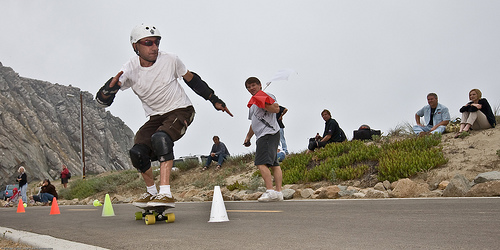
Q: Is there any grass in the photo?
A: Yes, there is grass.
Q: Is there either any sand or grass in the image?
A: Yes, there is grass.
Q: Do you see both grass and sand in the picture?
A: No, there is grass but no sand.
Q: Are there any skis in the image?
A: No, there are no skis.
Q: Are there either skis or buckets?
A: No, there are no skis or buckets.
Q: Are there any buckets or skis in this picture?
A: No, there are no skis or buckets.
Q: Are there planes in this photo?
A: No, there are no planes.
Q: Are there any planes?
A: No, there are no planes.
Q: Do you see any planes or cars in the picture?
A: No, there are no planes or cars.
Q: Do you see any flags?
A: Yes, there is a flag.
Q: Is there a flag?
A: Yes, there is a flag.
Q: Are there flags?
A: Yes, there is a flag.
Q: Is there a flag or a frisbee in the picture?
A: Yes, there is a flag.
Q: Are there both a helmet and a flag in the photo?
A: Yes, there are both a flag and a helmet.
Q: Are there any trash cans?
A: No, there are no trash cans.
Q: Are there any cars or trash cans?
A: No, there are no trash cans or cars.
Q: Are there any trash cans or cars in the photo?
A: No, there are no trash cans or cars.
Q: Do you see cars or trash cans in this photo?
A: No, there are no trash cans or cars.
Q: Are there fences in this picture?
A: No, there are no fences.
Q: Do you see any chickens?
A: No, there are no chickens.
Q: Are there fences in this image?
A: No, there are no fences.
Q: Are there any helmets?
A: Yes, there is a helmet.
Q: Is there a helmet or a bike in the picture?
A: Yes, there is a helmet.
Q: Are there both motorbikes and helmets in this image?
A: No, there is a helmet but no motorcycles.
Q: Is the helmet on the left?
A: Yes, the helmet is on the left of the image.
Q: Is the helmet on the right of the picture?
A: No, the helmet is on the left of the image.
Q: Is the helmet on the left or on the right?
A: The helmet is on the left of the image.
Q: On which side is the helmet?
A: The helmet is on the left of the image.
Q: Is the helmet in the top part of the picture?
A: Yes, the helmet is in the top of the image.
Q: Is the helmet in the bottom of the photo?
A: No, the helmet is in the top of the image.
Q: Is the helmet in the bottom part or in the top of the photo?
A: The helmet is in the top of the image.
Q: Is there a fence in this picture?
A: No, there are no fences.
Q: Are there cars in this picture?
A: No, there are no cars.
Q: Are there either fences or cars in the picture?
A: No, there are no cars or fences.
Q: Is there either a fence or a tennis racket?
A: No, there are no fences or rackets.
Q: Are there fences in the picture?
A: No, there are no fences.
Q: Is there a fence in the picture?
A: No, there are no fences.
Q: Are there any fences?
A: No, there are no fences.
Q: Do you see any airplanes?
A: No, there are no airplanes.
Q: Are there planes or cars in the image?
A: No, there are no planes or cars.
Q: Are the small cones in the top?
A: No, the cones are in the bottom of the image.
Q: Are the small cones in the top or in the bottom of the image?
A: The cones are in the bottom of the image.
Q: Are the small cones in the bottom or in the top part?
A: The cones are in the bottom of the image.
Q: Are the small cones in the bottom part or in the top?
A: The cones are in the bottom of the image.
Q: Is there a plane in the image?
A: No, there are no airplanes.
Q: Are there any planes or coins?
A: No, there are no planes or coins.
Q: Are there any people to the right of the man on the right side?
A: Yes, there are people to the right of the man.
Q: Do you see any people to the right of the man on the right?
A: Yes, there are people to the right of the man.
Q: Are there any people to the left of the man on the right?
A: No, the people are to the right of the man.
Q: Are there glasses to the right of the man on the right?
A: No, there are people to the right of the man.